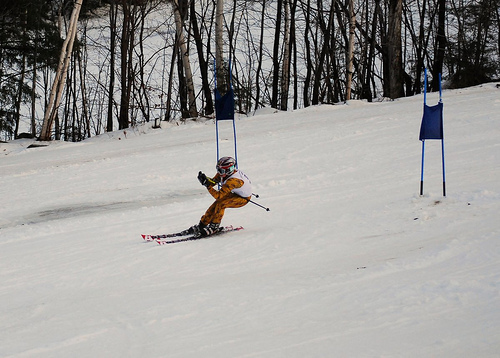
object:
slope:
[3, 79, 499, 260]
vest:
[220, 169, 255, 198]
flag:
[419, 68, 449, 199]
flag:
[211, 57, 239, 163]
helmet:
[216, 156, 237, 175]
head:
[216, 156, 237, 176]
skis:
[154, 226, 247, 248]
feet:
[193, 227, 220, 238]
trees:
[213, 0, 234, 117]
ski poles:
[206, 179, 272, 212]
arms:
[209, 177, 234, 200]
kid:
[184, 154, 254, 238]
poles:
[440, 139, 446, 196]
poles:
[232, 123, 239, 162]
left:
[211, 58, 240, 160]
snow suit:
[197, 171, 250, 232]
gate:
[208, 67, 451, 196]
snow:
[364, 258, 389, 274]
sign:
[212, 87, 237, 121]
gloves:
[198, 171, 209, 187]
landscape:
[5, 73, 496, 358]